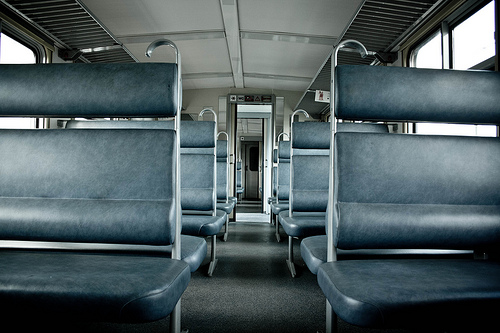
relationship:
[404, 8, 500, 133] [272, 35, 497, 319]
glass window next to seating area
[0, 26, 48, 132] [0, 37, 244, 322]
window next to seating area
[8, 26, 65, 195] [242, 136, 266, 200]
window on door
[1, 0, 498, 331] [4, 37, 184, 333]
train car has seat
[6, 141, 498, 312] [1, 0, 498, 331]
area in train car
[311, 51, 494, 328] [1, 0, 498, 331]
seat on train car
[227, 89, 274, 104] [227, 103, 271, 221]
sign on top of door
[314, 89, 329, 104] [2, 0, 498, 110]
sign hangs from ceiling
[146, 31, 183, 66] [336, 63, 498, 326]
hook on top of seat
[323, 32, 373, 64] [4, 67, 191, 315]
hook on top of seat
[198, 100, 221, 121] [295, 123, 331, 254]
hook on top of seat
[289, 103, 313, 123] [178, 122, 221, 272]
hook on top of seat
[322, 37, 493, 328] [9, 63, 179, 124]
seat has rest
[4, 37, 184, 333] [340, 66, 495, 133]
seat has rest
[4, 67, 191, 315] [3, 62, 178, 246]
seat has backrest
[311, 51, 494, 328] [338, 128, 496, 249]
seat has backrest